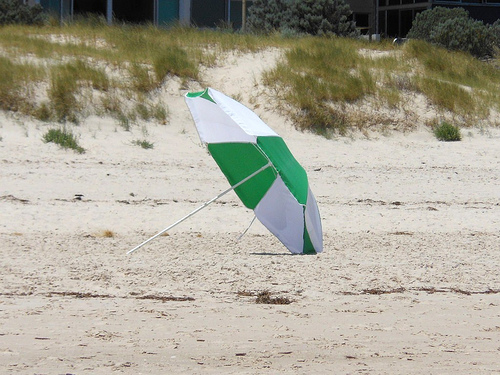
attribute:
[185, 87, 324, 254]
umbrella — green, white, for sun, tilted over, striped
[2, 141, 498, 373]
beach — sandy, white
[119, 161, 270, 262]
pole — white, long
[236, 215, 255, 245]
strap — white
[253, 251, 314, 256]
shadow — small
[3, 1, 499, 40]
building — barely visible, barely seen, in background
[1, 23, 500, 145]
sand hill — tall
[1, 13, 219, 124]
grass — green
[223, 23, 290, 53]
grass — green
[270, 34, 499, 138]
grass — green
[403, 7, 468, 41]
shrub — large, small, green, in background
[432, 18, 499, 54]
shrub — large, green, in background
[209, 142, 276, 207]
panel — green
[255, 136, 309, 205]
panel — green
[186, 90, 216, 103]
panel — green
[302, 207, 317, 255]
panel — green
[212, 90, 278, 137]
panel — white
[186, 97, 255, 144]
panel — white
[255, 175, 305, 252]
panel — white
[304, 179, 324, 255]
panel — white